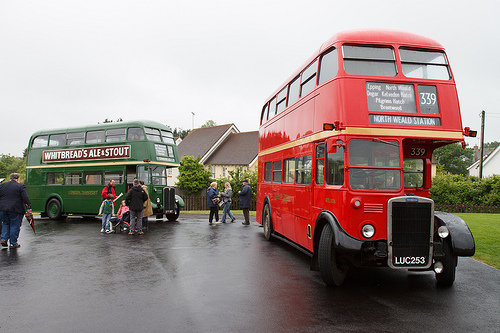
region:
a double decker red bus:
[249, 28, 473, 285]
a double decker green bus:
[18, 125, 179, 225]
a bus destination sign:
[372, 112, 436, 124]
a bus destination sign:
[151, 154, 176, 160]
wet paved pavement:
[4, 207, 496, 326]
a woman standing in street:
[205, 178, 220, 223]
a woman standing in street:
[219, 177, 235, 223]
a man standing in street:
[233, 176, 253, 219]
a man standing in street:
[0, 170, 42, 248]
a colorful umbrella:
[21, 207, 40, 236]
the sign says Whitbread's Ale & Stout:
[43, 145, 133, 162]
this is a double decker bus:
[2, 111, 247, 258]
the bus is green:
[31, 107, 178, 237]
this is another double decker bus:
[258, 15, 472, 286]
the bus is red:
[251, 31, 484, 303]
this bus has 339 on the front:
[417, 82, 439, 114]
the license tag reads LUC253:
[390, 250, 435, 275]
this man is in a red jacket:
[101, 165, 118, 204]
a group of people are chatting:
[98, 168, 158, 244]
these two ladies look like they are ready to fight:
[201, 180, 243, 241]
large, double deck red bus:
[257, 30, 476, 292]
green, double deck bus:
[24, 119, 184, 221]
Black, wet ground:
[0, 215, 498, 330]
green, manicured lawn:
[181, 209, 498, 269]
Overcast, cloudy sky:
[1, 1, 498, 153]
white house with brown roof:
[179, 122, 259, 184]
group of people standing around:
[1, 170, 253, 253]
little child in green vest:
[97, 195, 116, 232]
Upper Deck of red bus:
[257, 31, 460, 151]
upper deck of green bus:
[29, 120, 179, 165]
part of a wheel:
[297, 245, 349, 289]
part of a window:
[369, 147, 389, 166]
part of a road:
[200, 242, 241, 291]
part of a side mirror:
[322, 97, 346, 179]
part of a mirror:
[217, 238, 249, 276]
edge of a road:
[479, 256, 491, 268]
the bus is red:
[232, 92, 369, 308]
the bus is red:
[341, 176, 407, 326]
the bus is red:
[328, 144, 439, 314]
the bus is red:
[324, 133, 385, 325]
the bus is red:
[305, 182, 362, 327]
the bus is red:
[298, 139, 368, 279]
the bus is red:
[278, 148, 338, 288]